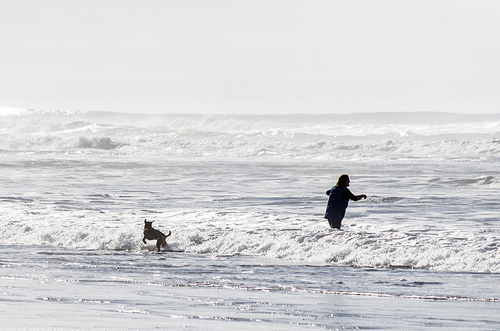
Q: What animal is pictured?
A: A dog.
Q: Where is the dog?
A: In the ocean.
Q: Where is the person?
A: In the ocean.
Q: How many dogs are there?
A: One.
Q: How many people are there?
A: One.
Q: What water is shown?
A: An ocean.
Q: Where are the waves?
A: In the ocean.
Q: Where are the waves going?
A: Towards the shore.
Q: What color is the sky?
A: Grey.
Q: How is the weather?
A: Overcast.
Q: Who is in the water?
A: A person.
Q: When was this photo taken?
A: During the day.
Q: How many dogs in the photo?
A: One.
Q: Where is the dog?
A: The water.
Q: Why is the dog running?
A: Water is cold.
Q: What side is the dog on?
A: Left.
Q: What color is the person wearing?
A: Black.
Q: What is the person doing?
A: Standing in the water.